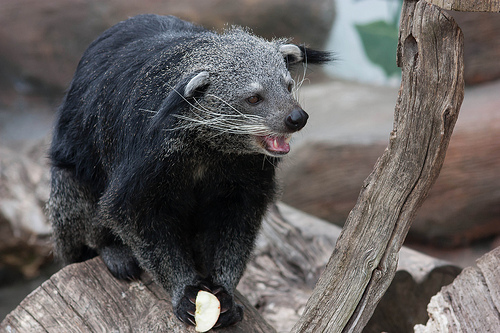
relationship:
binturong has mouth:
[47, 12, 335, 329] [254, 131, 294, 156]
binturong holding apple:
[47, 12, 335, 329] [192, 289, 222, 332]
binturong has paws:
[47, 12, 335, 329] [164, 278, 246, 332]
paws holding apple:
[164, 278, 246, 332] [192, 289, 222, 332]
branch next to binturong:
[285, 2, 499, 330] [47, 12, 335, 329]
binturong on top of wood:
[47, 12, 335, 329] [4, 239, 278, 332]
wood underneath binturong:
[4, 239, 278, 332] [47, 12, 335, 329]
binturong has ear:
[47, 12, 335, 329] [183, 70, 209, 99]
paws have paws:
[164, 278, 246, 332] [171, 283, 209, 328]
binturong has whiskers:
[47, 12, 335, 329] [135, 82, 272, 140]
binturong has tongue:
[47, 12, 335, 329] [265, 135, 289, 152]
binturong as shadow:
[47, 12, 335, 329] [362, 264, 462, 330]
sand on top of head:
[153, 27, 288, 156] [174, 31, 308, 167]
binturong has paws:
[47, 12, 335, 329] [171, 283, 209, 328]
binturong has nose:
[47, 12, 335, 329] [285, 109, 309, 130]